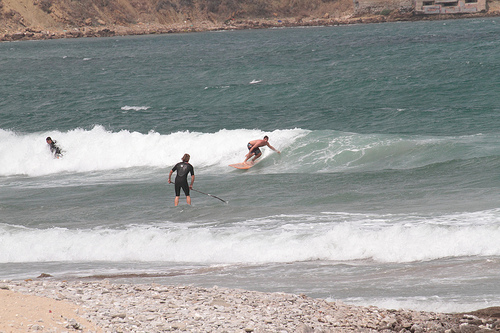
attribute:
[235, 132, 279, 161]
man — surfing, white, standing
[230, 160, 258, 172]
board — small, brown, orange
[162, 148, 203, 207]
woman — tall, standing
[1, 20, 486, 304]
water — white, blue, green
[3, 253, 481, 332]
beach — brown, white,  not wearing shirt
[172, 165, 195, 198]
wetsuit —  black,   short sleeved,  wet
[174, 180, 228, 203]
ore —  long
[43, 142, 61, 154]
shirt —  Man's,  dark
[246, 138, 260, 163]
shorts —  dark,  Man's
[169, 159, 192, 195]
wetsuit —  wet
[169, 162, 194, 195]
suit —  wet,  black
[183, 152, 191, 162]
hair —  brown,   Person's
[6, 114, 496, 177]
waves —  crashing in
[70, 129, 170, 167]
tops —  white